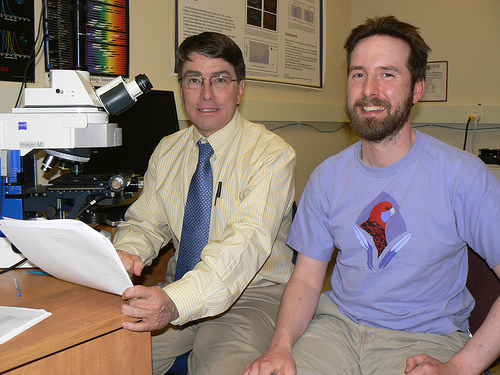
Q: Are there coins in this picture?
A: No, there are no coins.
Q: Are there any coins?
A: No, there are no coins.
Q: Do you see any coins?
A: No, there are no coins.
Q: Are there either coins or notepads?
A: No, there are no coins or notepads.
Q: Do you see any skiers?
A: No, there are no skiers.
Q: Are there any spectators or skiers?
A: No, there are no skiers or spectators.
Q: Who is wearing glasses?
A: The man is wearing glasses.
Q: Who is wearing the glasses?
A: The man is wearing glasses.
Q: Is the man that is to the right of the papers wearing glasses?
A: Yes, the man is wearing glasses.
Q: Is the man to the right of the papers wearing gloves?
A: No, the man is wearing glasses.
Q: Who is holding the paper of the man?
A: The man is holding the paper.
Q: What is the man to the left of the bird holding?
A: The man is holding the paper.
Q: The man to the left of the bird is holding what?
A: The man is holding the paper.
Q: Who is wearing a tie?
A: The man is wearing a tie.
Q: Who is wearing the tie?
A: The man is wearing a tie.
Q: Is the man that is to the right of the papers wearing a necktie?
A: Yes, the man is wearing a necktie.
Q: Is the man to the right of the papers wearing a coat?
A: No, the man is wearing a necktie.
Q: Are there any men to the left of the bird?
A: Yes, there is a man to the left of the bird.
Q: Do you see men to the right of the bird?
A: No, the man is to the left of the bird.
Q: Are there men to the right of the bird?
A: No, the man is to the left of the bird.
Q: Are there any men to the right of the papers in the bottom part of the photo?
A: Yes, there is a man to the right of the papers.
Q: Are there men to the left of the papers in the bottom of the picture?
A: No, the man is to the right of the papers.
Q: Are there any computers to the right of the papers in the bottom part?
A: No, there is a man to the right of the papers.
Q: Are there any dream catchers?
A: No, there are no dream catchers.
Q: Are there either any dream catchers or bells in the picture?
A: No, there are no dream catchers or bells.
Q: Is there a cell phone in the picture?
A: No, there are no cell phones.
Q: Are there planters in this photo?
A: No, there are no planters.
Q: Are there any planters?
A: No, there are no planters.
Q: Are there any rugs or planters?
A: No, there are no planters or rugs.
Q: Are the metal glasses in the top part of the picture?
A: Yes, the glasses are in the top of the image.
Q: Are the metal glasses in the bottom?
A: No, the glasses are in the top of the image.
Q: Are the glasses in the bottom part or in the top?
A: The glasses are in the top of the image.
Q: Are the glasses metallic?
A: Yes, the glasses are metallic.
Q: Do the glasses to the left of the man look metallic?
A: Yes, the glasses are metallic.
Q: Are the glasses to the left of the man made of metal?
A: Yes, the glasses are made of metal.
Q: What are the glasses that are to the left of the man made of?
A: The glasses are made of metal.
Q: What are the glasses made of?
A: The glasses are made of metal.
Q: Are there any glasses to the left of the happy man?
A: Yes, there are glasses to the left of the man.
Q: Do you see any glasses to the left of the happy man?
A: Yes, there are glasses to the left of the man.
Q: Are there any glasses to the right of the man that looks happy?
A: No, the glasses are to the left of the man.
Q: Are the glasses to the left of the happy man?
A: Yes, the glasses are to the left of the man.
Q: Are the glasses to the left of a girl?
A: No, the glasses are to the left of the man.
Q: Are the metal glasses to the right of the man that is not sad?
A: No, the glasses are to the left of the man.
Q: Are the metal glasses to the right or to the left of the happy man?
A: The glasses are to the left of the man.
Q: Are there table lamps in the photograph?
A: No, there are no table lamps.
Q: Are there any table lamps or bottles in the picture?
A: No, there are no table lamps or bottles.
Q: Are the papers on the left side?
A: Yes, the papers are on the left of the image.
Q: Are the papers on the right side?
A: No, the papers are on the left of the image.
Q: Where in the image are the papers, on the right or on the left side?
A: The papers are on the left of the image.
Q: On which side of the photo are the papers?
A: The papers are on the left of the image.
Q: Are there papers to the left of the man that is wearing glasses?
A: Yes, there are papers to the left of the man.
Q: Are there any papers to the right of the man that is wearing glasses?
A: No, the papers are to the left of the man.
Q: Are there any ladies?
A: No, there are no ladies.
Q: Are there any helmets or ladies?
A: No, there are no ladies or helmets.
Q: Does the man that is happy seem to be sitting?
A: Yes, the man is sitting.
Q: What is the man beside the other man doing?
A: The man is sitting.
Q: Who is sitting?
A: The man is sitting.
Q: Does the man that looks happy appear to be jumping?
A: No, the man is sitting.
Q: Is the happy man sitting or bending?
A: The man is sitting.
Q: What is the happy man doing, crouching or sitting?
A: The man is sitting.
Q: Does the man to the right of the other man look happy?
A: Yes, the man is happy.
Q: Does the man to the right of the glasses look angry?
A: No, the man is happy.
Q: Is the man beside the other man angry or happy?
A: The man is happy.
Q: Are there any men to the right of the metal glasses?
A: Yes, there is a man to the right of the glasses.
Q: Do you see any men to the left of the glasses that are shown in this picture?
A: No, the man is to the right of the glasses.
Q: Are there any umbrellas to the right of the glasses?
A: No, there is a man to the right of the glasses.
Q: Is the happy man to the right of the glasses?
A: Yes, the man is to the right of the glasses.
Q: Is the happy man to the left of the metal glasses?
A: No, the man is to the right of the glasses.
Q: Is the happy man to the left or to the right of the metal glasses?
A: The man is to the right of the glasses.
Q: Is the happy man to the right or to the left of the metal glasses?
A: The man is to the right of the glasses.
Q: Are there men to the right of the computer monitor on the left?
A: Yes, there is a man to the right of the computer monitor.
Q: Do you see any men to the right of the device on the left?
A: Yes, there is a man to the right of the computer monitor.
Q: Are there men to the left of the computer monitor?
A: No, the man is to the right of the computer monitor.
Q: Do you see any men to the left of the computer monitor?
A: No, the man is to the right of the computer monitor.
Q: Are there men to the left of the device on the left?
A: No, the man is to the right of the computer monitor.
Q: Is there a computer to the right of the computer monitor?
A: No, there is a man to the right of the computer monitor.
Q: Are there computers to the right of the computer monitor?
A: No, there is a man to the right of the computer monitor.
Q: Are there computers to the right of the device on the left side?
A: No, there is a man to the right of the computer monitor.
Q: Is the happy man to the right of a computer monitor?
A: Yes, the man is to the right of a computer monitor.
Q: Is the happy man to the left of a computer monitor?
A: No, the man is to the right of a computer monitor.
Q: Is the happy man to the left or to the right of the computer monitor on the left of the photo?
A: The man is to the right of the computer monitor.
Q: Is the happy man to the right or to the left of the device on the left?
A: The man is to the right of the computer monitor.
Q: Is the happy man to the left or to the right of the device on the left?
A: The man is to the right of the computer monitor.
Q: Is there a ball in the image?
A: No, there are no balls.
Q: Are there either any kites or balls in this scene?
A: No, there are no balls or kites.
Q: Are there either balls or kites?
A: No, there are no balls or kites.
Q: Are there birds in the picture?
A: Yes, there is a bird.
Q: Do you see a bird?
A: Yes, there is a bird.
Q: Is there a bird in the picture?
A: Yes, there is a bird.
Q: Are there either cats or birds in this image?
A: Yes, there is a bird.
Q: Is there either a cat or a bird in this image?
A: Yes, there is a bird.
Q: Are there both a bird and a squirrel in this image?
A: No, there is a bird but no squirrels.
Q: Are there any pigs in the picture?
A: No, there are no pigs.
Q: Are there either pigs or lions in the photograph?
A: No, there are no pigs or lions.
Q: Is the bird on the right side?
A: Yes, the bird is on the right of the image.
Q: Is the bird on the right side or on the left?
A: The bird is on the right of the image.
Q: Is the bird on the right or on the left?
A: The bird is on the right of the image.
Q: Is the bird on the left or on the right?
A: The bird is on the right of the image.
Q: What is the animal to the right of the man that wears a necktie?
A: The animal is a bird.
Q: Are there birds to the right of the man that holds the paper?
A: Yes, there is a bird to the right of the man.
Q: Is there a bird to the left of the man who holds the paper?
A: No, the bird is to the right of the man.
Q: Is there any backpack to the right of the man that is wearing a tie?
A: No, there is a bird to the right of the man.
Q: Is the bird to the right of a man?
A: Yes, the bird is to the right of a man.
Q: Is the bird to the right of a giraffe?
A: No, the bird is to the right of a man.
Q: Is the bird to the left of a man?
A: No, the bird is to the right of a man.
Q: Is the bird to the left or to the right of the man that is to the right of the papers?
A: The bird is to the right of the man.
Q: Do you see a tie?
A: Yes, there is a tie.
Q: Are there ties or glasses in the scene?
A: Yes, there is a tie.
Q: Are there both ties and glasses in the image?
A: Yes, there are both a tie and glasses.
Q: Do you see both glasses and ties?
A: Yes, there are both a tie and glasses.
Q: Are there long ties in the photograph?
A: Yes, there is a long tie.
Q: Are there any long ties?
A: Yes, there is a long tie.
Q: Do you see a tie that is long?
A: Yes, there is a tie that is long.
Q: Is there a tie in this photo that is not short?
A: Yes, there is a long tie.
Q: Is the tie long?
A: Yes, the tie is long.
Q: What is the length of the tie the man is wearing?
A: The tie is long.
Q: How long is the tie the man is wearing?
A: The tie is long.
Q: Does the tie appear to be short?
A: No, the tie is long.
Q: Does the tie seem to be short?
A: No, the tie is long.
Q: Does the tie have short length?
A: No, the tie is long.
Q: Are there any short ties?
A: No, there is a tie but it is long.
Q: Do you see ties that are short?
A: No, there is a tie but it is long.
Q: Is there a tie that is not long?
A: No, there is a tie but it is long.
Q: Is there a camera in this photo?
A: No, there are no cameras.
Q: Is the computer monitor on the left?
A: Yes, the computer monitor is on the left of the image.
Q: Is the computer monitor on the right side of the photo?
A: No, the computer monitor is on the left of the image.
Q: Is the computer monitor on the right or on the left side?
A: The computer monitor is on the left of the image.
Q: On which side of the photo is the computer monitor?
A: The computer monitor is on the left of the image.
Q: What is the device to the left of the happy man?
A: The device is a computer monitor.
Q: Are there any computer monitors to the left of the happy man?
A: Yes, there is a computer monitor to the left of the man.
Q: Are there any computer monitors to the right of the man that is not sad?
A: No, the computer monitor is to the left of the man.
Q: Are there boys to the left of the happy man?
A: No, there is a computer monitor to the left of the man.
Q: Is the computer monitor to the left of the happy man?
A: Yes, the computer monitor is to the left of the man.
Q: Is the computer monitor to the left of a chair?
A: No, the computer monitor is to the left of the man.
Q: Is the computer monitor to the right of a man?
A: No, the computer monitor is to the left of a man.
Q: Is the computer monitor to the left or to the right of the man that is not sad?
A: The computer monitor is to the left of the man.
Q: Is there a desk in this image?
A: Yes, there is a desk.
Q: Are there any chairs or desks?
A: Yes, there is a desk.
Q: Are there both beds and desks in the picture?
A: No, there is a desk but no beds.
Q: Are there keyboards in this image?
A: No, there are no keyboards.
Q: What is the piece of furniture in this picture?
A: The piece of furniture is a desk.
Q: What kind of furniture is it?
A: The piece of furniture is a desk.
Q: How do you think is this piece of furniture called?
A: This is a desk.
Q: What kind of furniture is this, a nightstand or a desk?
A: This is a desk.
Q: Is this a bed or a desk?
A: This is a desk.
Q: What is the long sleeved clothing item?
A: The clothing item is a dress shirt.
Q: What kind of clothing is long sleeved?
A: The clothing is a dress shirt.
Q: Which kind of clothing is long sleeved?
A: The clothing is a dress shirt.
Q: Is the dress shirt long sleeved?
A: Yes, the dress shirt is long sleeved.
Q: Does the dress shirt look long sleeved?
A: Yes, the dress shirt is long sleeved.